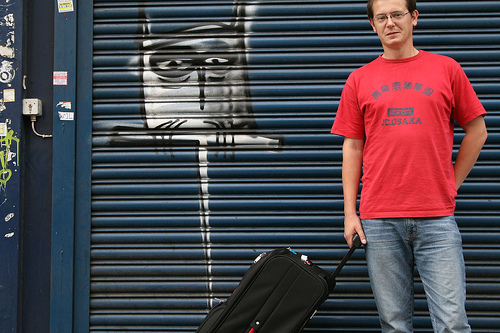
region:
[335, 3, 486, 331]
man in a red t-shirt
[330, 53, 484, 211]
red t-shirt with blue writing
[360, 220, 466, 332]
faded blue jeans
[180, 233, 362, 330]
black rolling suitcase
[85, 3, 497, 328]
dark blue garage door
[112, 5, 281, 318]
silver owl on garage door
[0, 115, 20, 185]
green paint splatters left of the door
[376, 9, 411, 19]
the man's glasses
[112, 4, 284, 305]
black and silver graffiti owl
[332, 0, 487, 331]
man standing next to a blue garage door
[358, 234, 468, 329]
a man wearing blue jeans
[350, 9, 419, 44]
a man wearing glasses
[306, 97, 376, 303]
a man holding the handle to a suitcase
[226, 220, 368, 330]
a black suitcase with a handle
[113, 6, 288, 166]
grafetti on a garage door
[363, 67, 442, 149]
a red shirt with a blue logo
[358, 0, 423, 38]
a man with short hair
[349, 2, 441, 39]
a man with brown hair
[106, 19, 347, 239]
a blue garage door with a painting on it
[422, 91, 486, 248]
a man with his hand behind his back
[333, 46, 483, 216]
the man is wearing a red shirt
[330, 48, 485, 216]
the man has a short sleeve shirt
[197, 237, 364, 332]
the man is holding luggage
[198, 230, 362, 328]
the luggage is black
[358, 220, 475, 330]
the man is wearing denim pants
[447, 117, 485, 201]
the man has one hand behind himself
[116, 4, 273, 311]
graffiti on the wall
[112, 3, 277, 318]
the graffiti is of an owl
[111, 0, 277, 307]
the graffiti is black and white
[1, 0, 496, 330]
the wall is blue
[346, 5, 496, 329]
man wearing red shirt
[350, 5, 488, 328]
man wearing blue jeans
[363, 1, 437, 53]
man wearing glasses with brown rims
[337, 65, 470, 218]
red shirt has blue lettering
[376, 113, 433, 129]
JC OSAKA written on shirt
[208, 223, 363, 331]
man holding black luggage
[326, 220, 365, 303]
handle on suitcase is black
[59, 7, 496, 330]
garage door is blue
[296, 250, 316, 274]
lock on suitcase is silver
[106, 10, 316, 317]
graffiti drawing of cat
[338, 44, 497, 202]
a red shirt with blue writing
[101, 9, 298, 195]
graffiti on the rolling door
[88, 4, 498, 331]
a blue metal rolling door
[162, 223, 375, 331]
a rolling black suitcase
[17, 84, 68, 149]
an electrical switch for door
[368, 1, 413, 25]
glasses on man's face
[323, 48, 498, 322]
red shirt and jeans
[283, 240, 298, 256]
a blue tag on suitcase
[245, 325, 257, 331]
a red tag on suitcase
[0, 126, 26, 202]
green paint on wall